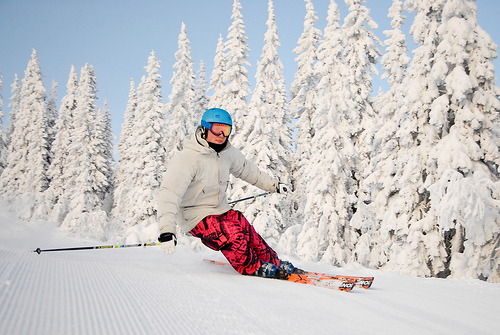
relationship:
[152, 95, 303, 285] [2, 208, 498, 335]
man on mountain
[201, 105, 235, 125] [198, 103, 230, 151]
helmet on head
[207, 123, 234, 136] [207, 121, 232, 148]
goggles on face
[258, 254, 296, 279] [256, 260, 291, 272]
boots with buckles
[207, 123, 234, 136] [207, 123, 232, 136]
goggles have goggles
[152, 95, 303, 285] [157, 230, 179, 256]
man wearing gloves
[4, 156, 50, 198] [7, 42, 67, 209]
bottom of tree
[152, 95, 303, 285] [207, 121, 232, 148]
man has face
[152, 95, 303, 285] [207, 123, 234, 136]
man wearing goggles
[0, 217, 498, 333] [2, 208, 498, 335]
snow on mountain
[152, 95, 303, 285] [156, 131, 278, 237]
man wearing coat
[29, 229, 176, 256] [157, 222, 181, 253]
ski pole in hand